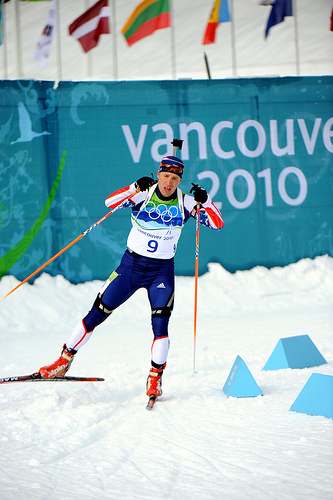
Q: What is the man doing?
A: Skiing.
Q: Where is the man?
A: On the snow.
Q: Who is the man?
A: An athlete.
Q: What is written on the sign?
A: Vancouver 2010.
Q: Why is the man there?
A: To compete in the race.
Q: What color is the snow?
A: White.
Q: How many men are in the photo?
A: One.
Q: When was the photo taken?
A: During the day.